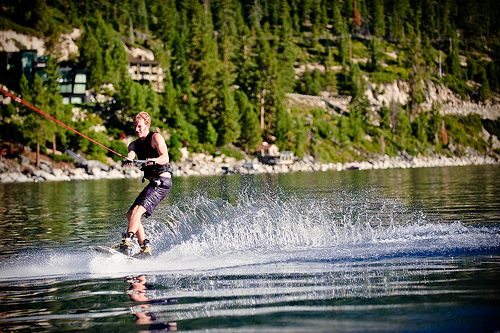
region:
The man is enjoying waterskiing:
[5, 57, 475, 277]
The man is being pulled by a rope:
[30, 60, 495, 296]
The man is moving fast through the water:
[0, 42, 490, 309]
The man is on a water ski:
[21, 55, 487, 290]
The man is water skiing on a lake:
[6, 73, 474, 289]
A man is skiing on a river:
[10, 63, 485, 283]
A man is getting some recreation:
[20, 65, 485, 276]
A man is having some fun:
[18, 28, 495, 323]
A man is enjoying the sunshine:
[5, 52, 496, 308]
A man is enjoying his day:
[40, 65, 482, 322]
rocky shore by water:
[13, 155, 499, 187]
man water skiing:
[101, 113, 188, 272]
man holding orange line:
[0, 66, 172, 270]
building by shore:
[0, 42, 156, 184]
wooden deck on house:
[7, 41, 169, 112]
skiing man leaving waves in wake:
[98, 111, 491, 258]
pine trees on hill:
[8, 11, 498, 161]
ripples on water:
[3, 261, 497, 331]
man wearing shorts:
[111, 114, 179, 267]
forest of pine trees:
[13, 9, 494, 162]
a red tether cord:
[3, 84, 139, 180]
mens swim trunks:
[127, 172, 186, 226]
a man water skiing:
[112, 101, 182, 276]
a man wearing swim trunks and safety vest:
[114, 99, 199, 251]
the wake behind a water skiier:
[162, 177, 492, 285]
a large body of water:
[195, 164, 491, 312]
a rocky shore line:
[172, 152, 493, 176]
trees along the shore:
[85, 17, 325, 139]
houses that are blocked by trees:
[9, 36, 206, 116]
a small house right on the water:
[250, 141, 314, 181]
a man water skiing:
[19, 51, 304, 316]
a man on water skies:
[47, 69, 312, 325]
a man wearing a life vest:
[78, 71, 253, 298]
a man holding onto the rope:
[115, 104, 201, 246]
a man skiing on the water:
[109, 68, 218, 319]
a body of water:
[190, 169, 490, 323]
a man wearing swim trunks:
[77, 83, 212, 283]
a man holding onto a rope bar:
[39, 93, 216, 239]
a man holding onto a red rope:
[19, 38, 235, 271]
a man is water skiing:
[62, 70, 194, 262]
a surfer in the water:
[110, 103, 176, 261]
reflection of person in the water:
[116, 276, 184, 331]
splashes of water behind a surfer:
[116, 179, 477, 277]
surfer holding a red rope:
[2, 79, 178, 267]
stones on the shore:
[176, 146, 487, 173]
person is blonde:
[116, 108, 173, 156]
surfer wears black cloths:
[111, 108, 178, 252]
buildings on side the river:
[20, 43, 177, 113]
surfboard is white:
[79, 239, 166, 271]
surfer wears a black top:
[119, 106, 182, 185]